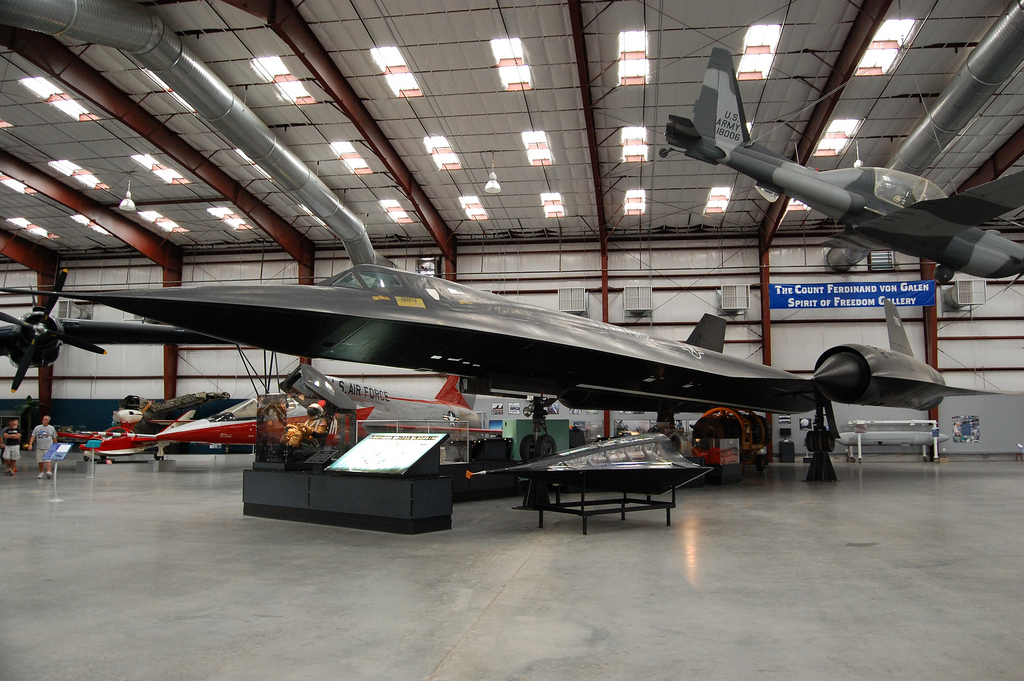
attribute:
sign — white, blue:
[767, 272, 936, 318]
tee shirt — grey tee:
[27, 405, 65, 447]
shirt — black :
[0, 417, 24, 453]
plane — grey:
[663, 85, 1018, 251]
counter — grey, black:
[278, 439, 516, 558]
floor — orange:
[252, 508, 755, 655]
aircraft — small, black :
[416, 385, 691, 535]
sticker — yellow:
[382, 287, 465, 339]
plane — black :
[135, 314, 768, 512]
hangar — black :
[21, 208, 737, 500]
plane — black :
[302, 205, 907, 518]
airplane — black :
[106, 257, 875, 495]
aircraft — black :
[100, 250, 960, 560]